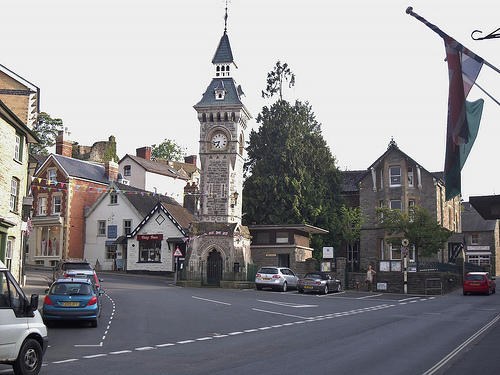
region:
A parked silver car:
[245, 255, 295, 295]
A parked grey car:
[290, 265, 340, 295]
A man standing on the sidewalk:
[360, 260, 375, 285]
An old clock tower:
[170, 0, 250, 295]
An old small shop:
[110, 195, 195, 275]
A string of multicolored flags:
[20, 165, 205, 200]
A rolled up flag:
[400, 0, 495, 155]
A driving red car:
[455, 260, 495, 300]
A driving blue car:
[35, 271, 105, 322]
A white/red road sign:
[166, 243, 186, 284]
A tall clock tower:
[177, 0, 249, 306]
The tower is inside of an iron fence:
[171, 261, 251, 281]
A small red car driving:
[457, 263, 496, 304]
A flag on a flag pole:
[403, 9, 485, 206]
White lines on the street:
[168, 319, 291, 360]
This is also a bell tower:
[186, 22, 253, 108]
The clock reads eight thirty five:
[191, 116, 234, 152]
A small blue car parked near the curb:
[38, 270, 104, 326]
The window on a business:
[135, 232, 164, 267]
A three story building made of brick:
[33, 157, 81, 266]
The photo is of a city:
[18, 85, 405, 345]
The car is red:
[440, 252, 499, 292]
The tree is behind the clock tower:
[232, 80, 472, 322]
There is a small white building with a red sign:
[22, 138, 218, 308]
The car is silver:
[240, 258, 396, 313]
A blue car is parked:
[26, 272, 168, 350]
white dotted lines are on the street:
[123, 315, 470, 373]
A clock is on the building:
[191, 83, 280, 181]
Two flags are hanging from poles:
[395, 15, 495, 113]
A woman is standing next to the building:
[356, 258, 395, 305]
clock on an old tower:
[183, 2, 264, 288]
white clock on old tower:
[205, 124, 232, 158]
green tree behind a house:
[241, 58, 375, 288]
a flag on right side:
[388, 3, 498, 206]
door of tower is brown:
[198, 243, 228, 288]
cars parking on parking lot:
[248, 255, 371, 305]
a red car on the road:
[451, 265, 499, 307]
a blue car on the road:
[36, 273, 104, 330]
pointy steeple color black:
[205, 3, 242, 73]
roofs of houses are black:
[33, 144, 197, 235]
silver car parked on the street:
[254, 262, 299, 293]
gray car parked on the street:
[294, 266, 344, 296]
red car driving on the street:
[458, 267, 495, 298]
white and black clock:
[205, 126, 232, 151]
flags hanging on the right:
[403, 4, 498, 201]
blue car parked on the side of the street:
[41, 274, 104, 330]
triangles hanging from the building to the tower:
[26, 173, 209, 200]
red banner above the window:
[133, 231, 165, 243]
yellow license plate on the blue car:
[56, 298, 82, 309]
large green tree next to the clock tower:
[240, 58, 352, 253]